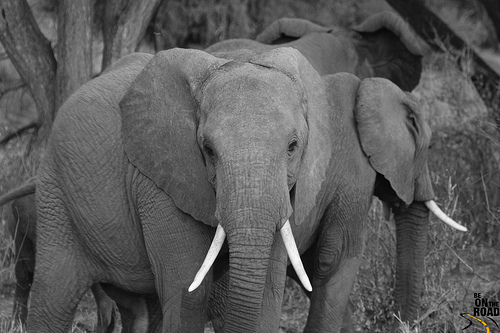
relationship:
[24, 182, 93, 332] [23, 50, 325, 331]
leg of an elephant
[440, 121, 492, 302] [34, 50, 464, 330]
grass behind elephant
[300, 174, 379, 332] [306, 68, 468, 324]
leg of elephant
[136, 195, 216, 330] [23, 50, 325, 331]
leg of elephant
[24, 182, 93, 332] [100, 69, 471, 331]
leg of elephant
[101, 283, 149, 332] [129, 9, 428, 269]
leg of elephant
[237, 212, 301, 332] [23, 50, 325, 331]
leg of elephant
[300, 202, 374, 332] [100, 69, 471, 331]
leg of elephant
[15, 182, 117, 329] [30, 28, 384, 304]
leg of elephant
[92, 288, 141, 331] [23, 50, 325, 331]
leg of elephant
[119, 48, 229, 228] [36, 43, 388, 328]
ear of elephant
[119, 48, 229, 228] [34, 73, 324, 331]
ear of elephant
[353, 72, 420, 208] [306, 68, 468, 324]
ear of elephant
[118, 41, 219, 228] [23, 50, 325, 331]
ear of elephant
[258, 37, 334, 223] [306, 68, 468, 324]
ear of elephant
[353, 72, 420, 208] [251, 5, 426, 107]
ear of elephant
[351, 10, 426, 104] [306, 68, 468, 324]
ear of elephant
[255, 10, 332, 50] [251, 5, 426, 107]
ear of elephant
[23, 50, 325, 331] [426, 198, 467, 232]
elephant has tusk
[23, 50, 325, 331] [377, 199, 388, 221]
elephant has tusk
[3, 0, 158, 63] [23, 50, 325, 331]
trunks behind elephant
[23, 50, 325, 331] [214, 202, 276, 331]
elephant has trunk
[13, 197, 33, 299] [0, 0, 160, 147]
stones behind tree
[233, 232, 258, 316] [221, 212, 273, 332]
ridges on trunk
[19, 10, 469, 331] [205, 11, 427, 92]
herd of elephant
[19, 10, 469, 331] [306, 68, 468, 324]
herd of elephant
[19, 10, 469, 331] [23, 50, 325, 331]
herd of elephant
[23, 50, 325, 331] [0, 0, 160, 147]
elephant standing among tree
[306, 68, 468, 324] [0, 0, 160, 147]
elephant standing among tree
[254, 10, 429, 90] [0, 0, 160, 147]
elephant standing among tree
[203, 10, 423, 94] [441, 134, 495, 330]
elephant standing in bush